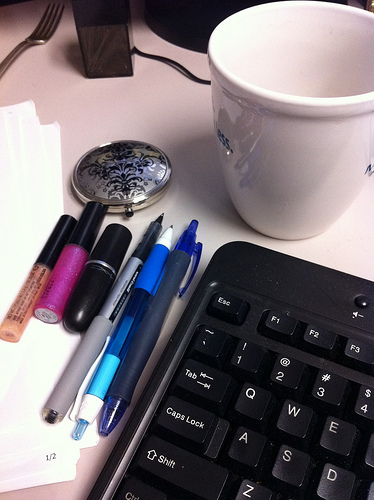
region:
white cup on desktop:
[187, 29, 372, 314]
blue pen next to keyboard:
[93, 211, 231, 428]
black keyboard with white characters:
[184, 312, 368, 497]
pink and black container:
[39, 195, 111, 334]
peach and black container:
[5, 204, 54, 354]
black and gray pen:
[62, 211, 144, 424]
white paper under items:
[22, 163, 134, 363]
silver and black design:
[50, 127, 192, 230]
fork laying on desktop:
[13, 8, 72, 94]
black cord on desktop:
[131, 39, 238, 95]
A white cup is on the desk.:
[203, 0, 372, 243]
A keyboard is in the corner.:
[140, 232, 372, 494]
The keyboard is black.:
[147, 242, 368, 498]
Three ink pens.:
[55, 211, 212, 437]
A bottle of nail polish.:
[9, 202, 124, 337]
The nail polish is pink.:
[30, 194, 118, 333]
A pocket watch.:
[58, 132, 174, 215]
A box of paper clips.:
[67, 0, 143, 80]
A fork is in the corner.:
[0, 0, 69, 92]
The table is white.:
[77, 91, 167, 121]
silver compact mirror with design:
[38, 86, 204, 223]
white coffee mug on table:
[187, 32, 361, 254]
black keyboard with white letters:
[209, 237, 372, 497]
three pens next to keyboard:
[53, 209, 246, 468]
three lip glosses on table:
[33, 205, 130, 300]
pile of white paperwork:
[5, 99, 125, 485]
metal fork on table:
[13, 11, 74, 74]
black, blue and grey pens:
[75, 209, 170, 448]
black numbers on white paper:
[28, 452, 73, 472]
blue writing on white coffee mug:
[201, 111, 245, 165]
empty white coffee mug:
[207, 1, 370, 243]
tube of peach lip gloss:
[0, 210, 69, 345]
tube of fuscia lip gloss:
[34, 197, 112, 327]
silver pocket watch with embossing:
[66, 136, 178, 223]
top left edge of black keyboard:
[71, 230, 371, 498]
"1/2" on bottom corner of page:
[40, 445, 61, 466]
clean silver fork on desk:
[2, 2, 70, 96]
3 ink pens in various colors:
[40, 207, 205, 445]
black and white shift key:
[129, 434, 218, 497]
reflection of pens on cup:
[212, 84, 277, 202]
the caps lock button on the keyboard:
[158, 394, 225, 454]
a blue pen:
[100, 212, 210, 433]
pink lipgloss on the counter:
[32, 193, 113, 322]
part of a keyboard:
[88, 227, 372, 498]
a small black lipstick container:
[61, 212, 150, 334]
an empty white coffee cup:
[185, 5, 372, 243]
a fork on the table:
[0, 4, 81, 78]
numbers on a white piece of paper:
[32, 445, 69, 468]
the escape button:
[207, 281, 244, 327]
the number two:
[269, 347, 295, 391]